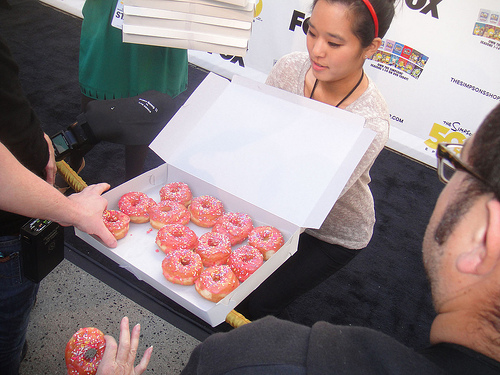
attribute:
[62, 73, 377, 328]
box — white, full, open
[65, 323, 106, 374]
donut — pink, grabbed, white, held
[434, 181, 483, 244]
sideburn — thick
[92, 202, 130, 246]
donut — grabbed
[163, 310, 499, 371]
shirt — black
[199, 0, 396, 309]
woman — looking, asian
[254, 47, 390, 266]
shirt — white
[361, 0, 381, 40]
headband — red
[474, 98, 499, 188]
hair — dark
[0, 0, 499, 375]
event — here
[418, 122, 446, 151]
numner — yellow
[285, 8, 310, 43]
cord — black\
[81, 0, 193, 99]
dress — green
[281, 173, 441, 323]
floor — marbled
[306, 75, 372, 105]
string — round